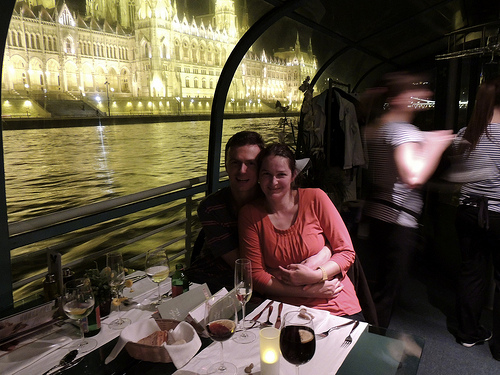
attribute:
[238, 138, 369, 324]
person — eating, sitting, couple, young, posing, pink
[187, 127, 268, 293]
person — eating, sitting, hugging, young, couple, posing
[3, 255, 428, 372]
table — set, blue, green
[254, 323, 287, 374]
candle — lit, white, nice, votive, frosted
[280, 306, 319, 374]
wine — full, red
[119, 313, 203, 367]
bread — empty, wicker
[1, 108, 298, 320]
water — calm, body 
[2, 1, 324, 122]
building — lit, historic, bright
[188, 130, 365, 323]
couple — young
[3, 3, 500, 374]
cruise — blurred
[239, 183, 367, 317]
shirt — colored, salmon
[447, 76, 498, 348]
woman — standing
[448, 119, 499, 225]
shirt — striped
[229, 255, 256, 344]
glass — fine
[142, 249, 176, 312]
glass — fine, white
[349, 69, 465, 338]
lady — blurred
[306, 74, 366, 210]
jacket — hanging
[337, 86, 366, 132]
jacket — hanging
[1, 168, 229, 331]
railing — protective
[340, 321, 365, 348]
fork — utensil, silver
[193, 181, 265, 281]
shirt — striped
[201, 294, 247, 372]
wine — red